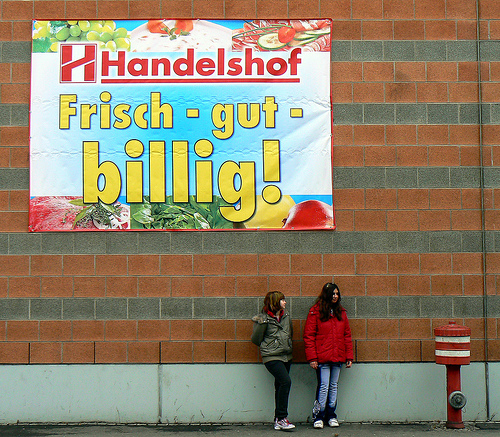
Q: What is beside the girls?
A: Fire hydrant.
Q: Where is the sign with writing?
A: On the wall.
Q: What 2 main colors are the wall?
A: Orange and gray.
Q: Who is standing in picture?
A: Both girls.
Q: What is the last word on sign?
A: Billig.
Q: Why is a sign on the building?
A: To advertise.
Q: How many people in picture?
A: Two.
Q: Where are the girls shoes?
A: On their feet.